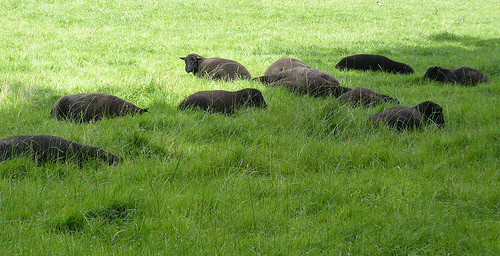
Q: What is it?
A: Lambs.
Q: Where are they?
A: On the grass.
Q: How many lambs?
A: 9.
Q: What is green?
A: Grass.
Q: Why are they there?
A: To rest.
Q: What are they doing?
A: Resting.